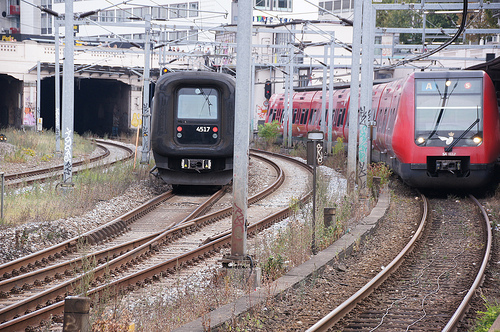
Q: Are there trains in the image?
A: Yes, there is a train.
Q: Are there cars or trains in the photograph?
A: Yes, there is a train.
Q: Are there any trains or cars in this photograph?
A: Yes, there is a train.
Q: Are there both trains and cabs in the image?
A: No, there is a train but no taxis.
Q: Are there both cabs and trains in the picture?
A: No, there is a train but no taxis.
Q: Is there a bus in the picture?
A: No, there are no buses.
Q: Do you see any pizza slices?
A: No, there are no pizza slices.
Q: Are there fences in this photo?
A: No, there are no fences.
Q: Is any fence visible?
A: No, there are no fences.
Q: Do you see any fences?
A: No, there are no fences.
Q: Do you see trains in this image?
A: Yes, there is a train.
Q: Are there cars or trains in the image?
A: Yes, there is a train.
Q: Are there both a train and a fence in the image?
A: No, there is a train but no fences.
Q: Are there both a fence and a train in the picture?
A: No, there is a train but no fences.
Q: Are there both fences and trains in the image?
A: No, there is a train but no fences.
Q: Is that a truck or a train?
A: That is a train.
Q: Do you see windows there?
A: Yes, there is a window.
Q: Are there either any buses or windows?
A: Yes, there is a window.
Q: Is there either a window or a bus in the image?
A: Yes, there is a window.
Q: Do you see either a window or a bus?
A: Yes, there is a window.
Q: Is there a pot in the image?
A: No, there are no pots.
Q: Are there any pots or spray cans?
A: No, there are no pots or spray cans.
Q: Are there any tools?
A: No, there are no tools.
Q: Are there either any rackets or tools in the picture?
A: No, there are no tools or rackets.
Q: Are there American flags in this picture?
A: No, there are no American flags.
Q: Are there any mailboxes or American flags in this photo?
A: No, there are no American flags or mailboxes.